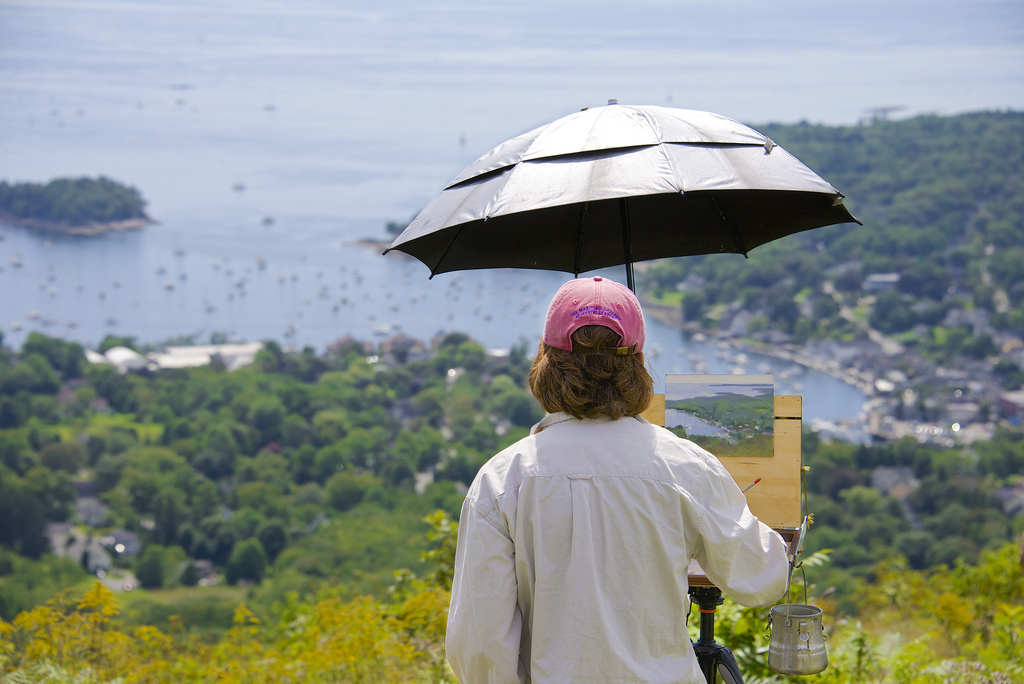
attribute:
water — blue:
[2, 7, 1017, 441]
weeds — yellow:
[2, 586, 1021, 682]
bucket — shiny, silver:
[767, 604, 828, 680]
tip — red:
[754, 476, 761, 499]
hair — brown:
[527, 327, 654, 422]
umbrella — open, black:
[381, 97, 862, 303]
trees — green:
[0, 175, 144, 229]